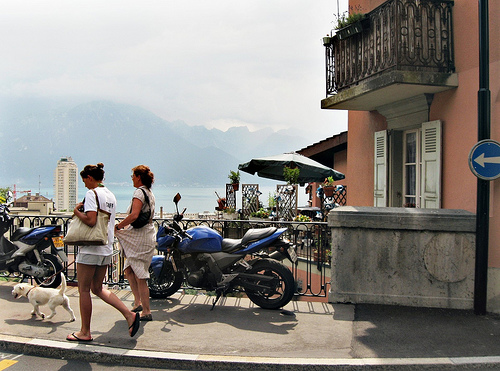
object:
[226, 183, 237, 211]
trellis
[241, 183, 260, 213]
trellis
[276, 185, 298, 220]
trellis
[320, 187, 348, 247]
trellis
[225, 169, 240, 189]
plant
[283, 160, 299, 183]
plant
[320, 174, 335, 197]
plant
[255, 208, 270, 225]
plant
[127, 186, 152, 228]
black bag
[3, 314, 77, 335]
shadow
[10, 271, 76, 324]
dog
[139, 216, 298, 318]
motorcycle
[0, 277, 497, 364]
sidewalk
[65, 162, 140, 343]
woman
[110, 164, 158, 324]
woman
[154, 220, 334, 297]
fence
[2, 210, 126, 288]
fence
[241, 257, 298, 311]
tire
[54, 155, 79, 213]
sky scraper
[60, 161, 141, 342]
person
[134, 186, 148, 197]
shoulder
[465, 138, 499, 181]
sign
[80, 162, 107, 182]
hair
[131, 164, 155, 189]
hair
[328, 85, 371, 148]
ground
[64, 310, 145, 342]
flops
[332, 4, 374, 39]
planter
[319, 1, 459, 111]
balcony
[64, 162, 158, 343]
lady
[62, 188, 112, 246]
purse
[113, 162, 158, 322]
person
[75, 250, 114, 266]
shorts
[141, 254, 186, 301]
front tire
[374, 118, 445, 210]
window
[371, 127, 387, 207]
shutter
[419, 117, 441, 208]
shutter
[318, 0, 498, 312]
apartment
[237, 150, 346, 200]
umbrella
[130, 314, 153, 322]
shoes